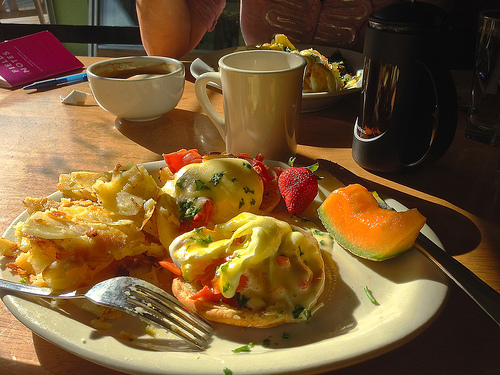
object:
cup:
[356, 8, 462, 177]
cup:
[196, 43, 313, 167]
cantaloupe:
[321, 175, 427, 267]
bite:
[346, 191, 405, 232]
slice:
[314, 182, 434, 272]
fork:
[3, 273, 219, 348]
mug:
[192, 45, 309, 163]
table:
[1, 52, 500, 373]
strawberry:
[277, 156, 324, 219]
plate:
[0, 153, 456, 375]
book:
[0, 29, 85, 89]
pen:
[24, 73, 92, 96]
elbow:
[136, 1, 210, 61]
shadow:
[275, 134, 487, 262]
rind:
[315, 206, 415, 266]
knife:
[307, 156, 498, 332]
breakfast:
[1, 145, 433, 341]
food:
[5, 146, 428, 333]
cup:
[81, 51, 190, 131]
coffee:
[99, 69, 174, 79]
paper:
[55, 88, 101, 107]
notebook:
[0, 23, 84, 86]